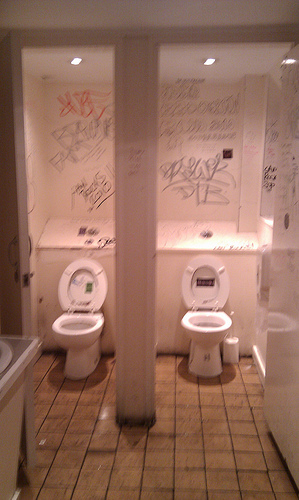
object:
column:
[115, 41, 156, 423]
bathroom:
[0, 1, 299, 500]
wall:
[44, 82, 115, 222]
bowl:
[51, 312, 104, 350]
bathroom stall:
[153, 75, 246, 357]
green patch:
[86, 282, 93, 292]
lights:
[71, 58, 82, 66]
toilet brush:
[230, 310, 234, 337]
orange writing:
[57, 89, 111, 120]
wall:
[157, 80, 243, 224]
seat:
[181, 311, 232, 379]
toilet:
[181, 253, 233, 378]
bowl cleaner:
[223, 310, 239, 363]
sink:
[0, 342, 12, 375]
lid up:
[182, 254, 231, 311]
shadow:
[179, 357, 236, 386]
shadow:
[48, 359, 108, 394]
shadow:
[117, 423, 155, 445]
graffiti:
[159, 84, 239, 205]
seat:
[51, 312, 104, 381]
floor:
[27, 355, 298, 500]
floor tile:
[176, 392, 200, 406]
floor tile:
[175, 434, 203, 450]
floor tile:
[141, 467, 173, 489]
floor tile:
[225, 406, 254, 420]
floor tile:
[176, 381, 199, 393]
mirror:
[259, 72, 292, 136]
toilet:
[52, 258, 109, 381]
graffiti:
[48, 90, 116, 211]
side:
[263, 42, 298, 500]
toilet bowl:
[180, 311, 232, 348]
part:
[40, 413, 92, 462]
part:
[48, 367, 89, 394]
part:
[223, 337, 239, 363]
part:
[0, 370, 26, 499]